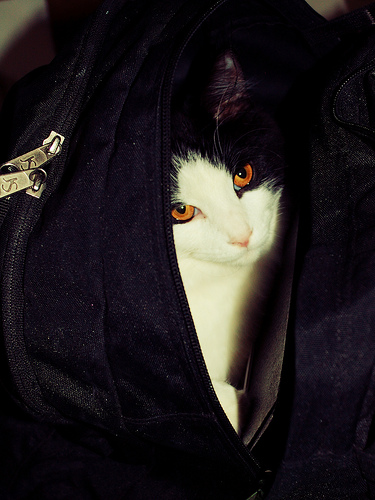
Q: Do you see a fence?
A: No, there are no fences.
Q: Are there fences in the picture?
A: No, there are no fences.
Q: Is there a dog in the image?
A: No, there are no dogs.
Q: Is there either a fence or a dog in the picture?
A: No, there are no dogs or fences.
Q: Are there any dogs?
A: No, there are no dogs.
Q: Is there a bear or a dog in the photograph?
A: No, there are no dogs or bears.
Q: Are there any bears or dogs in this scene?
A: No, there are no dogs or bears.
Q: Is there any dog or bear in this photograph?
A: No, there are no dogs or bears.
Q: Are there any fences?
A: No, there are no fences.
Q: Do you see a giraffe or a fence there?
A: No, there are no fences or giraffes.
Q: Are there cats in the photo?
A: Yes, there is a cat.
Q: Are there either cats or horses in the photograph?
A: Yes, there is a cat.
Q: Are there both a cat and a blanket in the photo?
A: No, there is a cat but no blankets.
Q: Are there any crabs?
A: No, there are no crabs.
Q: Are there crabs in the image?
A: No, there are no crabs.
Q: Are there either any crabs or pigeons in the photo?
A: No, there are no crabs or pigeons.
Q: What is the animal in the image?
A: The animal is a cat.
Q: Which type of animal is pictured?
A: The animal is a cat.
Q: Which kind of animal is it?
A: The animal is a cat.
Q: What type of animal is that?
A: This is a cat.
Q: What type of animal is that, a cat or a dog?
A: This is a cat.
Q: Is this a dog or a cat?
A: This is a cat.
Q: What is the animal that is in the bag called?
A: The animal is a cat.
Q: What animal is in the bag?
A: The animal is a cat.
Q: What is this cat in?
A: The cat is in the bag.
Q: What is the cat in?
A: The cat is in the bag.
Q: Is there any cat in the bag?
A: Yes, there is a cat in the bag.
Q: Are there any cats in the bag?
A: Yes, there is a cat in the bag.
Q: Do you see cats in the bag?
A: Yes, there is a cat in the bag.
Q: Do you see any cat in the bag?
A: Yes, there is a cat in the bag.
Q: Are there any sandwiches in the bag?
A: No, there is a cat in the bag.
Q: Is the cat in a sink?
A: No, the cat is in the bag.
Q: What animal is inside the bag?
A: The cat is inside the bag.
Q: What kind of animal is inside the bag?
A: The animal is a cat.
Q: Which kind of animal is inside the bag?
A: The animal is a cat.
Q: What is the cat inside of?
A: The cat is inside the bag.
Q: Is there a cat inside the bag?
A: Yes, there is a cat inside the bag.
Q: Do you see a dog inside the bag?
A: No, there is a cat inside the bag.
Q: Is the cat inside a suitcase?
A: No, the cat is inside a bag.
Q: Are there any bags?
A: Yes, there is a bag.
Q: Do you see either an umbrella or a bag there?
A: Yes, there is a bag.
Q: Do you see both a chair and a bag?
A: No, there is a bag but no chairs.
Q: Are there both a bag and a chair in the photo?
A: No, there is a bag but no chairs.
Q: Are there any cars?
A: No, there are no cars.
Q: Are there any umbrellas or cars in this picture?
A: No, there are no cars or umbrellas.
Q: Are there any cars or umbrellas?
A: No, there are no cars or umbrellas.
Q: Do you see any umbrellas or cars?
A: No, there are no cars or umbrellas.